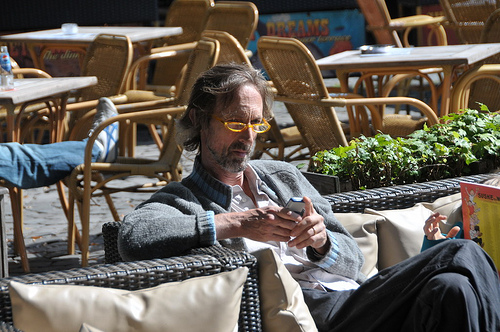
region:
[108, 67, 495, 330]
A seated man in a grey sweater.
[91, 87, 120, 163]
A white sneaker with blue stripes.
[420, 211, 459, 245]
A small child's hand.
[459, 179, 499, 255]
Part of the back cover of a child's book.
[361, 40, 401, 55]
A silver ashtray on a table.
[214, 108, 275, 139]
Eyeglasses being worn by a man.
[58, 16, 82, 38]
A small glass candle holder on a table.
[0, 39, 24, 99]
An empty bottle sitting on a table.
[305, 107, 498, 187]
A leafy bush behind the grey patio sofa.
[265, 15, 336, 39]
The word 'Dreams' in yellow and orange.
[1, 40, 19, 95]
Empty soda bottle on table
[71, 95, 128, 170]
Foot in brown chair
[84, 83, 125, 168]
White sneakers on foot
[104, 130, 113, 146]
Blue designs on sneaker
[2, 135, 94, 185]
Leg on brown chair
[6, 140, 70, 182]
Blue jeans on leg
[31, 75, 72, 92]
Top of grey table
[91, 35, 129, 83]
Backrest of brown chair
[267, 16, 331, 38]
Orangy yellow writing on poster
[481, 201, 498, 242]
Yellow paper in front of book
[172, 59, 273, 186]
man wearing amber colored glasses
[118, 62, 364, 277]
man looking at cellphone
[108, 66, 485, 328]
man wearing gray sweater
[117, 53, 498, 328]
man sitting with legs crossed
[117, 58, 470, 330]
man dressed in gray sitting on gray furniture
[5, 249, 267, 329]
front of gray chair with beige pillow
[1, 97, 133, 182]
one leg propped up on chair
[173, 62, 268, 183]
man with gray beard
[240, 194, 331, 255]
two hands holding cell phone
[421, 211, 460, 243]
child's hand outstretched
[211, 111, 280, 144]
Man is wearing glases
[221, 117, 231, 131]
Man's glasses are yellow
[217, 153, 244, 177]
Man has grey beard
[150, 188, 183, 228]
Man wearing grey sweater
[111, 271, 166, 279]
Man sitting on grey couch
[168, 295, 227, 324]
White pillow on couch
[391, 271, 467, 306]
Man wearing blue pants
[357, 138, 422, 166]
Green plants behind couch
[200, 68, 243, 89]
Man has grey hair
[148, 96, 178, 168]
Brown chair behind man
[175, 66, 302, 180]
a man wearing yellow glasses.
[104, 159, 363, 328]
a gray sweater.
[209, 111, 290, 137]
hipster style sun glasses.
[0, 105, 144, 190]
a foot resting on a chair.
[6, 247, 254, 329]
a white pillow on a chair.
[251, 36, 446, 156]
a brown chair near a table.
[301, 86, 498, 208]
a row of green plants.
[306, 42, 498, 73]
a table surrounded by chairs.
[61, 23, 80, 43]
a jar on a table.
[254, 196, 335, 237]
a person using a smart device.